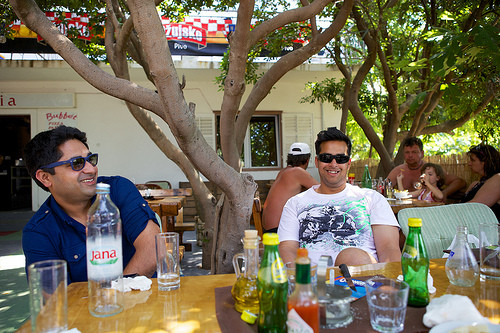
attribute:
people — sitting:
[33, 103, 500, 264]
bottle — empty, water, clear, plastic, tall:
[87, 188, 127, 296]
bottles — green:
[253, 214, 419, 299]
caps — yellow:
[259, 214, 429, 254]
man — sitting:
[30, 139, 127, 287]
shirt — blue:
[19, 203, 182, 299]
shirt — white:
[298, 175, 362, 265]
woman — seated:
[456, 144, 486, 196]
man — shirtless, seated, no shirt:
[264, 143, 309, 235]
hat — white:
[279, 138, 314, 163]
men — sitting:
[30, 111, 412, 286]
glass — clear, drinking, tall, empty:
[30, 262, 84, 332]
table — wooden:
[56, 245, 491, 329]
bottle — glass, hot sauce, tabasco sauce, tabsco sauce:
[290, 255, 318, 330]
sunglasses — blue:
[43, 153, 99, 179]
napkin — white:
[434, 289, 488, 331]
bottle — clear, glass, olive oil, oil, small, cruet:
[217, 227, 284, 301]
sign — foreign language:
[6, 13, 319, 69]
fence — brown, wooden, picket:
[349, 146, 495, 212]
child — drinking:
[414, 153, 449, 205]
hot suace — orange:
[291, 306, 318, 331]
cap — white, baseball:
[290, 140, 318, 162]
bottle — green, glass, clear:
[407, 214, 432, 304]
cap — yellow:
[408, 216, 421, 231]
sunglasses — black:
[317, 146, 354, 168]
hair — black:
[34, 127, 85, 162]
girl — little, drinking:
[417, 166, 440, 200]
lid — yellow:
[409, 221, 427, 229]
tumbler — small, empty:
[353, 284, 412, 332]